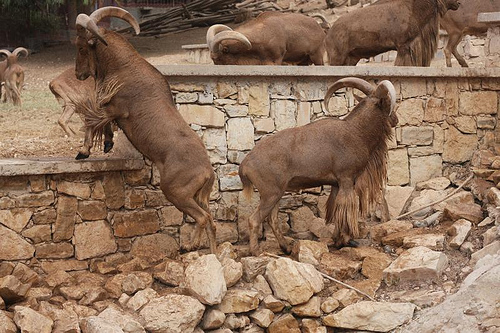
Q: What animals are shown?
A: Goat.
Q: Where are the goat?
A: In the habitat.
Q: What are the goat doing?
A: Walking.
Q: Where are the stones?
A: Piled together.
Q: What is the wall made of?
A: Stone/.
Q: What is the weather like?
A: Sunny.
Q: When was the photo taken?
A: Morning.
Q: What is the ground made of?
A: Grass, dirt and rocks.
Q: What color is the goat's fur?
A: Brown.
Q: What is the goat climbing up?
A: A fence.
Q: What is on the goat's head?
A: Horns.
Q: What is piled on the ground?
A: Rocks.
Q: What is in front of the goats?
A: Rock wall.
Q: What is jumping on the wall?
A: A ram.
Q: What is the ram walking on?
A: Rocks.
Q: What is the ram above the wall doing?
A: Grazing.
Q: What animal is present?
A: Ram.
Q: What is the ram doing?
A: Standing.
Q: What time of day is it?
A: Daytime.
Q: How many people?
A: None.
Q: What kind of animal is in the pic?
A: Ram.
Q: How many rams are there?
A: Seven.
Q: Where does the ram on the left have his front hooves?
A: A rock wall.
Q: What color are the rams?
A: Brown.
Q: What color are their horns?
A: White.